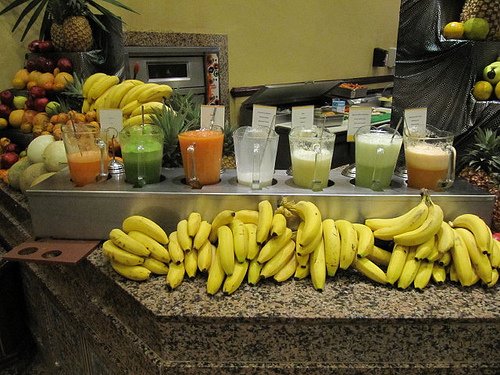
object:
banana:
[290, 200, 322, 269]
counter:
[58, 239, 499, 319]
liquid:
[177, 131, 226, 186]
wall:
[0, 1, 401, 92]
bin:
[27, 164, 496, 241]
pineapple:
[50, 1, 91, 52]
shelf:
[0, 16, 105, 153]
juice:
[121, 144, 164, 183]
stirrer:
[255, 113, 278, 177]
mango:
[29, 85, 47, 98]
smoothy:
[289, 151, 334, 190]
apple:
[0, 87, 17, 105]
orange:
[15, 69, 30, 81]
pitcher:
[232, 123, 280, 185]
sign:
[250, 103, 277, 134]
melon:
[43, 141, 70, 171]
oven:
[124, 48, 212, 126]